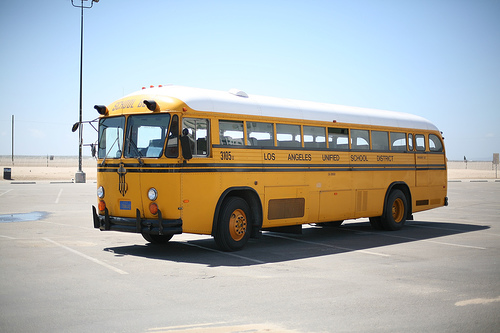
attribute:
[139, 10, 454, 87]
sky — clear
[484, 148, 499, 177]
street sign — white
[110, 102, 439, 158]
school bus — yellow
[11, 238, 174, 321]
parking — paved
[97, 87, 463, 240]
bus — big, yellow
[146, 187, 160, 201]
headlight — shiny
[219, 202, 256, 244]
tire — big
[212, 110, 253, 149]
window — small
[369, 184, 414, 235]
wheels — rubber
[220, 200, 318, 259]
bus wheel — yellow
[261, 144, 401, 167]
words — black, long, small, logo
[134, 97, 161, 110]
light fixtures — black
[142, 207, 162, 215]
reflectors — circular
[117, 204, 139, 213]
license plate — blue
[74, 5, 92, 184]
light post — tall